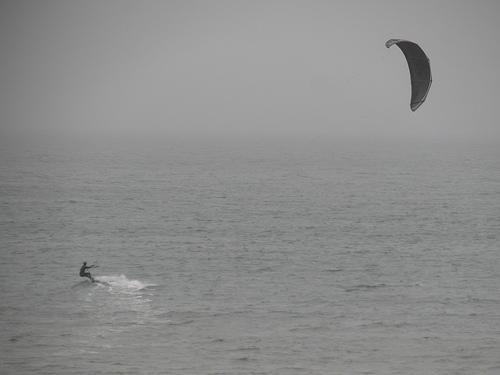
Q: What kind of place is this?
A: It is an ocean.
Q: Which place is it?
A: It is an ocean.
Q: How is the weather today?
A: It is overcast.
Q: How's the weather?
A: It is overcast.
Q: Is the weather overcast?
A: Yes, it is overcast.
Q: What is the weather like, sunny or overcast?
A: It is overcast.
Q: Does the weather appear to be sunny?
A: No, it is overcast.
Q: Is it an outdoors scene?
A: Yes, it is outdoors.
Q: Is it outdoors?
A: Yes, it is outdoors.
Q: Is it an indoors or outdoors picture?
A: It is outdoors.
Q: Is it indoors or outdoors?
A: It is outdoors.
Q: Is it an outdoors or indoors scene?
A: It is outdoors.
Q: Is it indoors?
A: No, it is outdoors.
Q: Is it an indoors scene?
A: No, it is outdoors.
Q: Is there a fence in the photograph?
A: No, there are no fences.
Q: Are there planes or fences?
A: No, there are no fences or planes.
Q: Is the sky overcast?
A: Yes, the sky is overcast.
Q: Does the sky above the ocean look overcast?
A: Yes, the sky is overcast.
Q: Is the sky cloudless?
A: No, the sky is overcast.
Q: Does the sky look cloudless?
A: No, the sky is overcast.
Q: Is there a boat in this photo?
A: No, there are no boats.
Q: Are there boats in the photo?
A: No, there are no boats.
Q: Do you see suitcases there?
A: No, there are no suitcases.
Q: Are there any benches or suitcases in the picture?
A: No, there are no suitcases or benches.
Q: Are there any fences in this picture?
A: No, there are no fences.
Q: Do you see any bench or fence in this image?
A: No, there are no fences or benches.